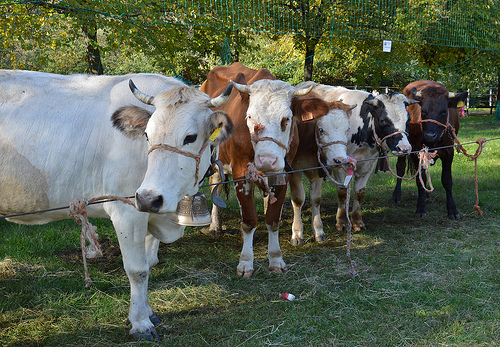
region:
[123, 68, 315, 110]
the horns on the cattle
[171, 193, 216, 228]
the bell on the neck of the cow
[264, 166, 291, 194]
the cowbell under the chin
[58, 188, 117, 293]
the rope tied to the wire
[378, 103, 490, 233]
the ropes on the face of the cattle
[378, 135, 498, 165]
the wire fence in front of the cows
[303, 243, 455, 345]
the hay on the grass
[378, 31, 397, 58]
the sign on the mesh fence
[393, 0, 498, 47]
the green mesh fence in front of the trees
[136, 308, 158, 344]
the black hooves of the cattle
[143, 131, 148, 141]
round shaped cow eye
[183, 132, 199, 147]
round shaped cow eye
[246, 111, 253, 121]
round shaped cow eye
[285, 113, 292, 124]
round shaped cow eye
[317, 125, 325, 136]
round shaped cow eye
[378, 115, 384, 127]
round shaped cow eye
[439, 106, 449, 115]
round shaped cow eye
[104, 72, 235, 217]
white colored cow head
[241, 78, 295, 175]
white colored cow head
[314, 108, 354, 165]
white colored cow head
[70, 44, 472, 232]
cows are behind fence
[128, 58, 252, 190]
white horns on cow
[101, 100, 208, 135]
cow has grey ears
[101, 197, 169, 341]
white legs on cow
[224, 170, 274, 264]
brown and white legs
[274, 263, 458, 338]
grass is green and brown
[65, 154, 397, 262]
grey wire fence in front of cows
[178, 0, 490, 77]
green mesh fence over cow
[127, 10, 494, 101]
green trees behind cows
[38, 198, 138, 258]
brown rope on fence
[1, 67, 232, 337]
A white cow standing in the grass.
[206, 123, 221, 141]
A yellow tag in the cow's ear.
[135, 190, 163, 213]
The nose of the cow.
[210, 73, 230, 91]
The brown hair on the cow.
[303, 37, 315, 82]
Part of a tree trunk.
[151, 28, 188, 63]
part of a green leafy tree.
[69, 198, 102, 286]
A knot of brown rope.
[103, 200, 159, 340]
The front legs of the cow.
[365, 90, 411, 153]
The black and white head of the cow.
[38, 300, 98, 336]
Part of the grass.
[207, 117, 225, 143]
Yellow tag on the ear.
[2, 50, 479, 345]
Cows on the grass.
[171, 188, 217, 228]
Bell on cow's neck.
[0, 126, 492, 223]
Cable above the ground.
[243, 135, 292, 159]
Rope around the cow.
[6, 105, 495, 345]
Green grass covering the ground.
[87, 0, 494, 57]
Black wrought iron fence.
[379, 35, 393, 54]
Sign on the fence.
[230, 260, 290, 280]
Tan hooves on the cow.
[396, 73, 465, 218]
Brown cow in the back.